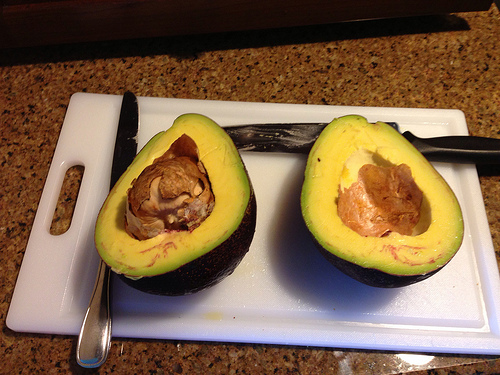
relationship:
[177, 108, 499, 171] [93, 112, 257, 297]
knife used to cut avocado half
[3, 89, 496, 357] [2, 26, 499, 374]
cutting board on granite countertop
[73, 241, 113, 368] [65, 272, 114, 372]
knife handle on knife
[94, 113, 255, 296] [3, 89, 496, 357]
avocado half on cutting board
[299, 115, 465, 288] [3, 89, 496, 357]
avocado half on cutting board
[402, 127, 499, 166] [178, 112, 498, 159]
handle on knife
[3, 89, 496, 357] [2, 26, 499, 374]
cutting board sitting on granite countertop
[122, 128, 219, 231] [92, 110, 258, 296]
meat in avocado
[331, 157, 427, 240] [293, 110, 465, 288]
meat in avocado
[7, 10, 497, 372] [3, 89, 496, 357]
countertop has cutting board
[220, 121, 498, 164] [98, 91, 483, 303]
knife cut avocado